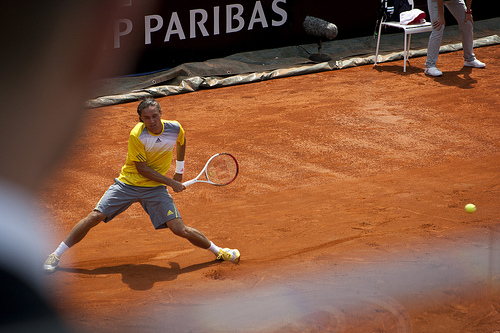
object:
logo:
[166, 210, 174, 216]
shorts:
[93, 175, 179, 231]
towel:
[399, 8, 426, 25]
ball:
[465, 205, 476, 211]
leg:
[58, 183, 127, 253]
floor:
[0, 45, 499, 332]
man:
[42, 97, 240, 275]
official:
[423, 0, 487, 77]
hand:
[431, 19, 447, 31]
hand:
[460, 9, 472, 19]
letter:
[135, 14, 165, 45]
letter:
[211, 7, 221, 36]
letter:
[223, 3, 246, 33]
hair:
[136, 97, 161, 116]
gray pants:
[93, 177, 178, 230]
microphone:
[303, 15, 338, 54]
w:
[215, 158, 229, 179]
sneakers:
[43, 255, 60, 274]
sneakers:
[218, 248, 243, 264]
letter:
[248, 3, 269, 31]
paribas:
[113, 0, 294, 45]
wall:
[0, 1, 497, 93]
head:
[137, 99, 163, 132]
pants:
[425, 0, 480, 61]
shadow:
[60, 255, 215, 295]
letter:
[188, 8, 210, 38]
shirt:
[115, 118, 189, 190]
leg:
[144, 193, 209, 251]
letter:
[161, 11, 187, 42]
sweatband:
[174, 161, 183, 173]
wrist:
[174, 166, 184, 176]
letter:
[269, 0, 289, 27]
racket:
[177, 150, 240, 192]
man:
[425, 0, 488, 76]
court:
[0, 0, 499, 333]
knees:
[430, 15, 444, 28]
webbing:
[206, 152, 236, 183]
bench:
[373, 0, 434, 73]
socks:
[52, 242, 68, 260]